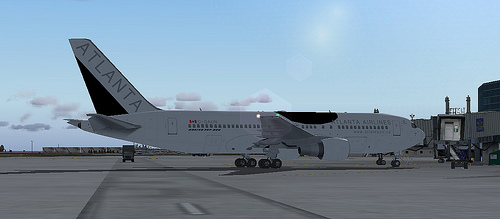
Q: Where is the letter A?
A: On the plane.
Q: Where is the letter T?
A: On the plane.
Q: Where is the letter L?
A: On the plane.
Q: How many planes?
A: One.